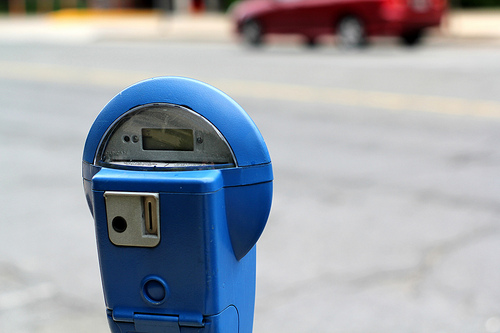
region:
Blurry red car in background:
[216, 0, 470, 57]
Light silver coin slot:
[95, 184, 176, 254]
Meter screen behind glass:
[100, 106, 240, 174]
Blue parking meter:
[49, 59, 297, 331]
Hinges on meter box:
[90, 292, 235, 331]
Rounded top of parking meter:
[45, 67, 294, 168]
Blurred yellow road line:
[240, 56, 490, 146]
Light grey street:
[294, 125, 476, 309]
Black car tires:
[236, 8, 383, 57]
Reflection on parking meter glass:
[79, 107, 259, 177]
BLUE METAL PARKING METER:
[79, 66, 279, 330]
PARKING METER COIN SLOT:
[130, 190, 161, 241]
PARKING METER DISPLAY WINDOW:
[132, 116, 208, 151]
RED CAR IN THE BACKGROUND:
[222, 1, 452, 51]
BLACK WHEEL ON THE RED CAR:
[325, 11, 380, 51]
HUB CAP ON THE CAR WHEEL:
[335, 10, 370, 47]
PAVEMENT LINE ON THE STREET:
[0, 55, 495, 115]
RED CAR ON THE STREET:
[210, 0, 490, 55]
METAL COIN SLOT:
[95, 190, 175, 250]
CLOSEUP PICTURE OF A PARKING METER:
[77, 68, 285, 331]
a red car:
[219, 1, 456, 55]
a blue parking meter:
[72, 82, 263, 330]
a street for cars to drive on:
[12, 41, 480, 331]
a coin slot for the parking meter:
[134, 194, 160, 240]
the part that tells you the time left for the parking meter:
[141, 127, 201, 153]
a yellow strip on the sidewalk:
[53, 3, 158, 30]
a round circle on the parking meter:
[134, 274, 167, 303]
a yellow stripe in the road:
[260, 85, 499, 145]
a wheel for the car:
[334, 15, 364, 47]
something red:
[191, 1, 202, 11]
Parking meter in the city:
[53, 21, 327, 327]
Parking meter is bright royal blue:
[65, 66, 292, 329]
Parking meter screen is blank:
[65, 75, 300, 200]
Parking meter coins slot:
[101, 164, 205, 282]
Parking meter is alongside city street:
[22, 40, 392, 331]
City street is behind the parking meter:
[5, 38, 491, 325]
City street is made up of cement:
[22, 35, 486, 315]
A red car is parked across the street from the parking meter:
[28, 0, 470, 316]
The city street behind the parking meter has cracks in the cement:
[15, 0, 470, 326]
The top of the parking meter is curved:
[55, 65, 337, 327]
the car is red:
[228, 1, 450, 51]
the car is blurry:
[224, 0, 451, 55]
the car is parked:
[228, 1, 450, 53]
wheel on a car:
[333, 14, 372, 49]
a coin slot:
[142, 197, 156, 239]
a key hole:
[107, 215, 130, 234]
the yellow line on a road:
[1, 54, 498, 127]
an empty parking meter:
[138, 124, 199, 152]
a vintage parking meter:
[77, 72, 274, 331]